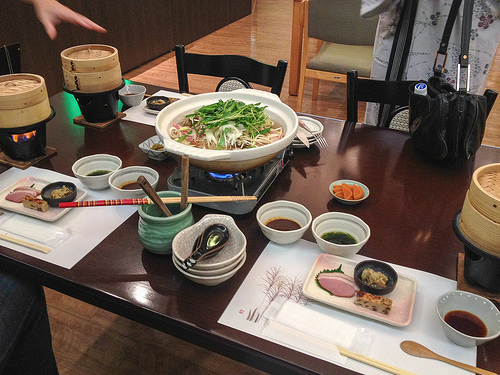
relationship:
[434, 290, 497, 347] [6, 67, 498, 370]
bowl on table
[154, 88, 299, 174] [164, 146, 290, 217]
bowl/food on burner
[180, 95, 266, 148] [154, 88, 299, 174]
vegetables in bowl/food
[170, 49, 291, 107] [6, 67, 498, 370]
chair in front of a table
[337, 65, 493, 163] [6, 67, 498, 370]
chair in front of a table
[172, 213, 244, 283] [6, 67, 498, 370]
bowls on table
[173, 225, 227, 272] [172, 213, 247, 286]
spoon on bowls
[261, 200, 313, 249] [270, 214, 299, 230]
bowl with sauce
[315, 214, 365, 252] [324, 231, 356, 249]
bowl with sauce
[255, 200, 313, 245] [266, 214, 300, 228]
bowl with sauce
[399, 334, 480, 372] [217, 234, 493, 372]
spoon on a mat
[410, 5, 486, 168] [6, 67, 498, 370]
bag on a table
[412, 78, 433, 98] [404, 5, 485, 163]
bottle sticking out of bag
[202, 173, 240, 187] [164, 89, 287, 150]
flame cooking food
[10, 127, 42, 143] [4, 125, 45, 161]
flame from a stove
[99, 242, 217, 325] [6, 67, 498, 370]
shadow on table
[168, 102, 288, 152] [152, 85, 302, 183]
food in bowl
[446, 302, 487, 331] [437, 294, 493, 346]
soup in bowl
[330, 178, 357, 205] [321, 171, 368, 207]
oranges in a bowl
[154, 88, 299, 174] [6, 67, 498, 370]
bowl/food in middle of table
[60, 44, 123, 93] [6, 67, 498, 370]
bamboo container on table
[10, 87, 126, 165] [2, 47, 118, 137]
flame heaters under boxes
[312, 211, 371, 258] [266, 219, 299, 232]
bowl have sauce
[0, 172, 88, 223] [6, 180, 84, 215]
rectangular plate has items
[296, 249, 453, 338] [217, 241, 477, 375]
dishes on a mat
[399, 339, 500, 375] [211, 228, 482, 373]
spoon on mat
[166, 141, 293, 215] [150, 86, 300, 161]
burner underneath bowl/food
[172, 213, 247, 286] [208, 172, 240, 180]
bowls on flame